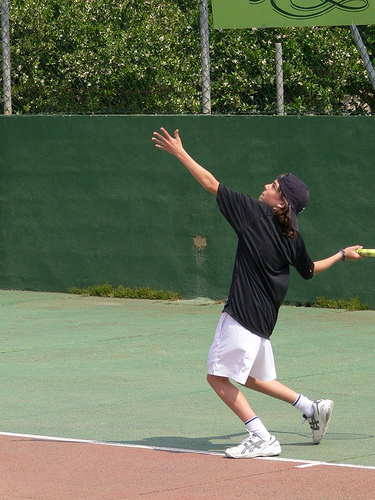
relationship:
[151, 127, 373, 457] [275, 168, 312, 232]
boy wearing hat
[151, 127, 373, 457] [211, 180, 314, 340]
boy wearing black shirt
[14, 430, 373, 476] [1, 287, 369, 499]
line on court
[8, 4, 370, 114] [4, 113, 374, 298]
bushes behind wall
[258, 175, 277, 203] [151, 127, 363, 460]
face of boy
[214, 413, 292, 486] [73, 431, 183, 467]
foot on line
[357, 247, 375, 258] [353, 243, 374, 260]
grip on racket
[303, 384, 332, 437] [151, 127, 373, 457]
shoe on boy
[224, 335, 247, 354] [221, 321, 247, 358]
ball in pocket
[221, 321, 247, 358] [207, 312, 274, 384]
pocket on short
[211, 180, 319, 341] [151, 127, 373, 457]
black shirt on boy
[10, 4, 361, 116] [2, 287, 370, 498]
trees outside tennis court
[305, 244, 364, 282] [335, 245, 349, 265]
right arm with watchband